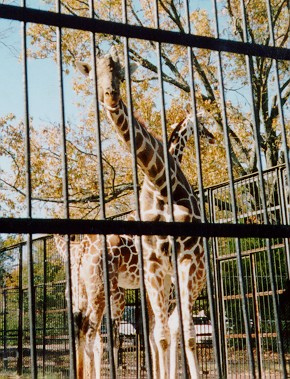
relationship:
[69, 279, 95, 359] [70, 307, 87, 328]
giraffe tail with hair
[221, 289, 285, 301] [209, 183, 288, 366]
rail on door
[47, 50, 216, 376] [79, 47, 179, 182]
giraffe craning neck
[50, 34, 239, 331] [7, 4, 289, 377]
giraffe behind bars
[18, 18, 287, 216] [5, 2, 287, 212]
leaves on a tree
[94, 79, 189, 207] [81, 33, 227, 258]
neck on a giraffe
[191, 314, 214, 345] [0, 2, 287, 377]
car behind cage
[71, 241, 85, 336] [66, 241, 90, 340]
giraffe tail with tail/black fur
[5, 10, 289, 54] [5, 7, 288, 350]
crossbar of fence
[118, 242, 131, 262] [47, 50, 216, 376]
spots on giraffe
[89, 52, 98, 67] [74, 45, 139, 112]
ossicone on giraffe head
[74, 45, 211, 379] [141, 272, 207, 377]
giraffe has legs